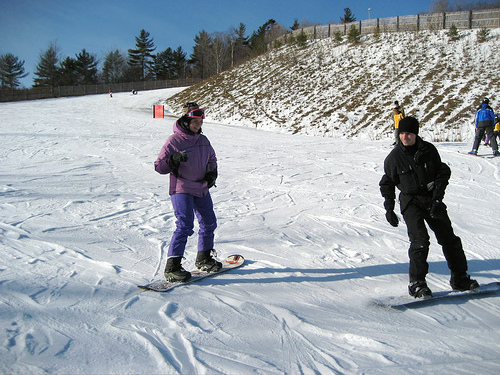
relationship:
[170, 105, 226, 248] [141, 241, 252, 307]
woman on snowboard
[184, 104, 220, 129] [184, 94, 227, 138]
goggles on head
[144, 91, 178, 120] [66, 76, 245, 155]
rise in ground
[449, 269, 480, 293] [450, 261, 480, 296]
edge of shoe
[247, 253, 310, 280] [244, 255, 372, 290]
edge of shade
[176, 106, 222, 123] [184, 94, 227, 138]
goggle on head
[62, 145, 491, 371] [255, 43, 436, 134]
snow on hill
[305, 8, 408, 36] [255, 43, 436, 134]
fence on hill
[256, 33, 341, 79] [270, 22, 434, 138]
green on slope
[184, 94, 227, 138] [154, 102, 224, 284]
head of woman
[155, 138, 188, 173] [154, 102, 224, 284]
arm of woman